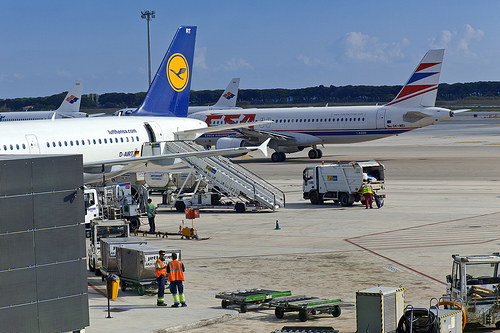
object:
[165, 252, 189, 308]
person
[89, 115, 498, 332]
tarmac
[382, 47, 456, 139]
tail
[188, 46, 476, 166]
plane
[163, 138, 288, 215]
steps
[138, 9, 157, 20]
light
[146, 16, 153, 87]
pole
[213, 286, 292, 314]
trailer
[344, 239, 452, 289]
line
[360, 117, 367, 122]
window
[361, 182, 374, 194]
vest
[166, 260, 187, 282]
top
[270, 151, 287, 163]
wheel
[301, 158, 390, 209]
truck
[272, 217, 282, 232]
cone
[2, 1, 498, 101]
sky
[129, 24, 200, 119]
fin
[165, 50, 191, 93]
logo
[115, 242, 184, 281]
container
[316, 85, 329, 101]
tree